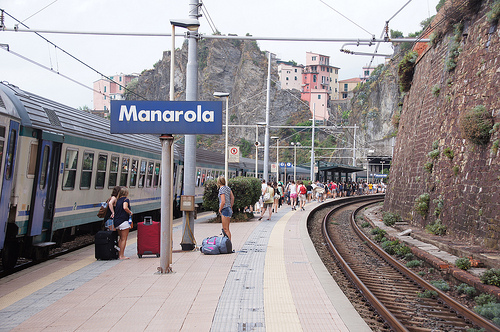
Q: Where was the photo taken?
A: It was taken at the city.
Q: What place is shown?
A: It is a city.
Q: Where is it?
A: This is at the city.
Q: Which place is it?
A: It is a city.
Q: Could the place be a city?
A: Yes, it is a city.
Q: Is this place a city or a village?
A: It is a city.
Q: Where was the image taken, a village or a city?
A: It was taken at a city.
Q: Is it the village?
A: No, it is the city.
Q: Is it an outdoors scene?
A: Yes, it is outdoors.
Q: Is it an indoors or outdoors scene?
A: It is outdoors.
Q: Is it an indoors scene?
A: No, it is outdoors.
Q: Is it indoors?
A: No, it is outdoors.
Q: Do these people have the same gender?
A: Yes, all the people are female.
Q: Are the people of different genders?
A: No, all the people are female.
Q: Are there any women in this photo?
A: Yes, there is a woman.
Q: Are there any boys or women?
A: Yes, there is a woman.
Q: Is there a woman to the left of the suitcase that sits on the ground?
A: Yes, there is a woman to the left of the suitcase.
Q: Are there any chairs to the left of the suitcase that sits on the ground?
A: No, there is a woman to the left of the suitcase.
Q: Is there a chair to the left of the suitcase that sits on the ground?
A: No, there is a woman to the left of the suitcase.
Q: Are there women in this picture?
A: Yes, there is a woman.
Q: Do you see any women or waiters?
A: Yes, there is a woman.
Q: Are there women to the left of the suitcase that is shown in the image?
A: Yes, there is a woman to the left of the suitcase.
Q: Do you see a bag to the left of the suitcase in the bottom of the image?
A: No, there is a woman to the left of the suitcase.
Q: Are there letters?
A: Yes, there are letters.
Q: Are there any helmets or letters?
A: Yes, there are letters.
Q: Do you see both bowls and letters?
A: No, there are letters but no bowls.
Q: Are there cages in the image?
A: No, there are no cages.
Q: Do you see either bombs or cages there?
A: No, there are no cages or bombs.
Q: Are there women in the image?
A: Yes, there is a woman.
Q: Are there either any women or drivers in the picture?
A: Yes, there is a woman.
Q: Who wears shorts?
A: The woman wears shorts.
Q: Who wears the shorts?
A: The woman wears shorts.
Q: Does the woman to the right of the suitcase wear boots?
A: No, the woman wears shorts.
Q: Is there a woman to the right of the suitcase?
A: Yes, there is a woman to the right of the suitcase.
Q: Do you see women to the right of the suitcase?
A: Yes, there is a woman to the right of the suitcase.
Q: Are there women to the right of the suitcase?
A: Yes, there is a woman to the right of the suitcase.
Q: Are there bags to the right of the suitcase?
A: No, there is a woman to the right of the suitcase.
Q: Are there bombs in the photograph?
A: No, there are no bombs.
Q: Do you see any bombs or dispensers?
A: No, there are no bombs or dispensers.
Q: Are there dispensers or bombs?
A: No, there are no bombs or dispensers.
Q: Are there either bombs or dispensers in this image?
A: No, there are no bombs or dispensers.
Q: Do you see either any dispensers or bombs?
A: No, there are no bombs or dispensers.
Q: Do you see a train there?
A: Yes, there is a train.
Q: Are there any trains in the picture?
A: Yes, there is a train.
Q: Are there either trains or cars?
A: Yes, there is a train.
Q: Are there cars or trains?
A: Yes, there is a train.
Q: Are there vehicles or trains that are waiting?
A: Yes, the train is waiting.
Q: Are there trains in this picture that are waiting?
A: Yes, there is a train that is waiting.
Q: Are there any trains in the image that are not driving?
A: Yes, there is a train that is waiting.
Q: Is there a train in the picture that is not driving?
A: Yes, there is a train that is waiting.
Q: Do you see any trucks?
A: No, there are no trucks.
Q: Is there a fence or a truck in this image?
A: No, there are no trucks or fences.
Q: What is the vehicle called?
A: The vehicle is a train.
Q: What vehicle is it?
A: The vehicle is a train.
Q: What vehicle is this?
A: This is a train.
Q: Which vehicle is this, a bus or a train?
A: This is a train.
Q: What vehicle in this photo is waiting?
A: The vehicle is a train.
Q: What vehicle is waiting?
A: The vehicle is a train.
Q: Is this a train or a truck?
A: This is a train.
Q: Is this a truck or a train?
A: This is a train.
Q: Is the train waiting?
A: Yes, the train is waiting.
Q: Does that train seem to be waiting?
A: Yes, the train is waiting.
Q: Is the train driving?
A: No, the train is waiting.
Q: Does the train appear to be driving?
A: No, the train is waiting.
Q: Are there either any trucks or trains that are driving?
A: No, there is a train but it is waiting.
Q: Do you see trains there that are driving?
A: No, there is a train but it is waiting.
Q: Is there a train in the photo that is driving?
A: No, there is a train but it is waiting.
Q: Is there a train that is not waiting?
A: No, there is a train but it is waiting.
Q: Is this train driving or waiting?
A: The train is waiting.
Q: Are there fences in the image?
A: No, there are no fences.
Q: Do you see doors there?
A: Yes, there is a door.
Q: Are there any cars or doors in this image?
A: Yes, there is a door.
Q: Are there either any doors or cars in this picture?
A: Yes, there is a door.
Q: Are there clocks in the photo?
A: No, there are no clocks.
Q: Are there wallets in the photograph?
A: No, there are no wallets.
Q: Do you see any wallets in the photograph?
A: No, there are no wallets.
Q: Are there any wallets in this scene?
A: No, there are no wallets.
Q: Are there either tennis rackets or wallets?
A: No, there are no wallets or tennis rackets.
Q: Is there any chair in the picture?
A: No, there are no chairs.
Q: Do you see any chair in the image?
A: No, there are no chairs.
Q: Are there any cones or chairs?
A: No, there are no chairs or cones.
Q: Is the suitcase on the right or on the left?
A: The suitcase is on the left of the image.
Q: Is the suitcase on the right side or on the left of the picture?
A: The suitcase is on the left of the image.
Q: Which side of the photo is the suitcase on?
A: The suitcase is on the left of the image.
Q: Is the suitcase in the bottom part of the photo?
A: Yes, the suitcase is in the bottom of the image.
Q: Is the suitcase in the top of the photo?
A: No, the suitcase is in the bottom of the image.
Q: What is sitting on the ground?
A: The suitcase is sitting on the ground.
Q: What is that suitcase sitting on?
A: The suitcase is sitting on the ground.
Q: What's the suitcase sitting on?
A: The suitcase is sitting on the ground.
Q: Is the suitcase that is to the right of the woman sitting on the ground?
A: Yes, the suitcase is sitting on the ground.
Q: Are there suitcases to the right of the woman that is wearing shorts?
A: No, the suitcase is to the left of the woman.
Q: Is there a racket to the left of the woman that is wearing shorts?
A: No, there is a suitcase to the left of the woman.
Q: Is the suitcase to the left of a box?
A: No, the suitcase is to the left of the woman.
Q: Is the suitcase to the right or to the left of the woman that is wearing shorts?
A: The suitcase is to the left of the woman.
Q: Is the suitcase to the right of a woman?
A: Yes, the suitcase is to the right of a woman.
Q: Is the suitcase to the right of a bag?
A: No, the suitcase is to the right of a woman.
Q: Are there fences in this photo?
A: No, there are no fences.